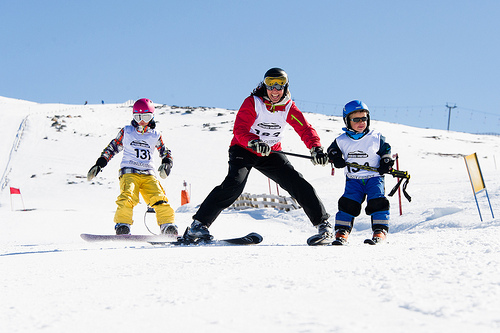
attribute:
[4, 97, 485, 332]
ground — here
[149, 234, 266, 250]
board — here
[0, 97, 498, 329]
snow — here, white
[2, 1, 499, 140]
sky — blue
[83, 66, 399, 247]
people — skiing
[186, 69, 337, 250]
woman — laughing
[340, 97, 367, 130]
helmet — blue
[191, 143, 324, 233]
legs — apart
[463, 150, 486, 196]
sign — yellow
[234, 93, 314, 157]
jacket — red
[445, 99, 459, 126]
post — black, electric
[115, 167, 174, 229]
pants — yellow, black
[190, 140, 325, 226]
pants — black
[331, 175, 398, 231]
pants — blue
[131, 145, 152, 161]
number — 131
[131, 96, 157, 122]
helmet — pink, red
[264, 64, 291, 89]
helmet — black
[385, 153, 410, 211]
pole — held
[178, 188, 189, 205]
cone — orange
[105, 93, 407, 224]
snowsuits — blue, white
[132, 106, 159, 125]
goggles — white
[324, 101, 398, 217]
gear — protective